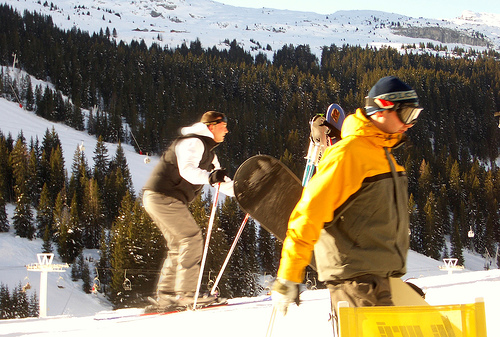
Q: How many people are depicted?
A: Two.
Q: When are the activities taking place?
A: Daytime.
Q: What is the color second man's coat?
A: Black.